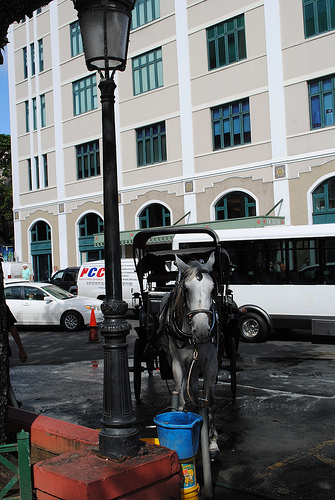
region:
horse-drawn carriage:
[134, 228, 237, 451]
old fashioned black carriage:
[134, 231, 237, 399]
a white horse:
[169, 254, 218, 454]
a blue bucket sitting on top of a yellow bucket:
[155, 409, 202, 455]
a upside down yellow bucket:
[177, 461, 199, 499]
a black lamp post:
[74, 4, 145, 455]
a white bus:
[174, 224, 332, 338]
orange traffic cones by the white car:
[87, 309, 100, 342]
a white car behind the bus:
[3, 282, 101, 326]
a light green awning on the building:
[93, 215, 283, 243]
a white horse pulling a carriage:
[129, 218, 252, 463]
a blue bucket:
[151, 403, 209, 460]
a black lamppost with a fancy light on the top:
[60, 0, 147, 473]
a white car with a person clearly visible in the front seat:
[1, 273, 109, 332]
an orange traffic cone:
[84, 305, 99, 327]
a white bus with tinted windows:
[169, 219, 333, 347]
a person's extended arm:
[0, 298, 31, 367]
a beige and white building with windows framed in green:
[0, 0, 334, 286]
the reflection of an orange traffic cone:
[85, 341, 100, 369]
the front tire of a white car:
[57, 306, 83, 333]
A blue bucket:
[141, 395, 218, 452]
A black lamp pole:
[77, 3, 137, 452]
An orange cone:
[81, 305, 104, 330]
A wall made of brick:
[29, 409, 190, 495]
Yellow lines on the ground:
[253, 423, 333, 482]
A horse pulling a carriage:
[156, 254, 241, 455]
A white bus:
[220, 215, 333, 345]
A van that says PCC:
[74, 255, 105, 283]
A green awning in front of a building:
[85, 215, 284, 244]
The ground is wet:
[239, 344, 302, 389]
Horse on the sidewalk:
[151, 251, 234, 455]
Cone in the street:
[82, 306, 100, 330]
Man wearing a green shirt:
[17, 261, 33, 280]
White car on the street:
[1, 275, 105, 337]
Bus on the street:
[167, 220, 334, 350]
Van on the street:
[76, 252, 147, 314]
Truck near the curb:
[43, 263, 85, 293]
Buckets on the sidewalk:
[137, 400, 211, 498]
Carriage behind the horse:
[125, 225, 243, 403]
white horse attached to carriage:
[131, 228, 242, 423]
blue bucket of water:
[155, 409, 204, 457]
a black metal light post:
[71, 0, 141, 455]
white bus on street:
[171, 224, 332, 340]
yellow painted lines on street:
[254, 433, 328, 486]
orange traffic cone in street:
[84, 307, 101, 345]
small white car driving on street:
[0, 279, 100, 327]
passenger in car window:
[24, 289, 41, 298]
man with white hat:
[19, 263, 31, 281]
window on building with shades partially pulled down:
[206, 102, 254, 154]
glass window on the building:
[136, 139, 143, 163]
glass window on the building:
[142, 137, 150, 161]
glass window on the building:
[150, 134, 156, 159]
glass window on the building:
[157, 131, 163, 156]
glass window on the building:
[210, 117, 217, 144]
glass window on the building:
[229, 114, 236, 140]